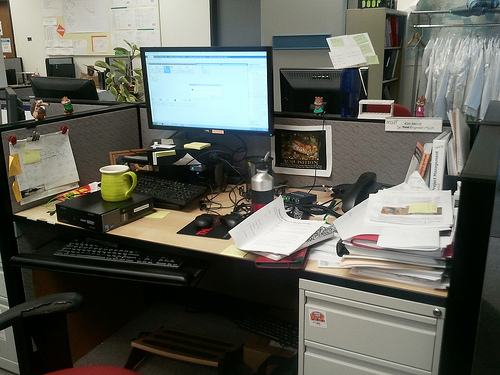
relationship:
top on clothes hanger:
[426, 41, 436, 99] [406, 35, 412, 49]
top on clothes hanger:
[440, 40, 445, 105] [413, 38, 423, 53]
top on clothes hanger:
[470, 47, 482, 114] [465, 26, 470, 36]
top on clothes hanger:
[484, 42, 493, 64] [488, 28, 495, 38]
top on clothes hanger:
[488, 52, 496, 103] [425, 23, 437, 38]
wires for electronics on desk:
[183, 130, 252, 215] [13, 184, 459, 305]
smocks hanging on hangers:
[419, 33, 498, 120] [406, 26, 426, 51]